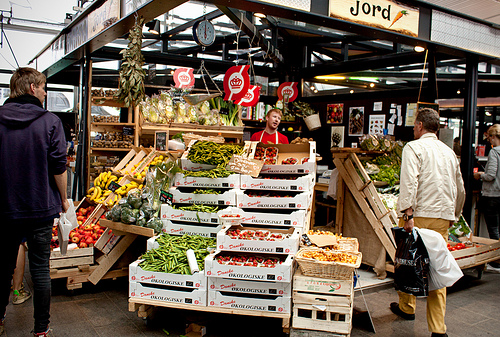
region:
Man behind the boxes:
[251, 110, 288, 143]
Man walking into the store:
[390, 109, 465, 334]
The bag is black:
[391, 224, 428, 295]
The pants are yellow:
[400, 216, 449, 332]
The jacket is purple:
[0, 95, 65, 226]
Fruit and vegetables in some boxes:
[50, 135, 360, 330]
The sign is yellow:
[330, 0, 415, 35]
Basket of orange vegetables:
[292, 245, 357, 275]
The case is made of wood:
[332, 148, 497, 275]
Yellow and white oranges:
[222, 62, 259, 108]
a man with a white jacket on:
[359, 114, 493, 217]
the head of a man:
[399, 86, 454, 166]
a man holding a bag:
[387, 148, 498, 281]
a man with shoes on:
[373, 258, 487, 328]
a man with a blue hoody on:
[10, 55, 136, 286]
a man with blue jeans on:
[0, 205, 61, 335]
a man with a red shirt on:
[251, 91, 316, 163]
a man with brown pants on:
[371, 206, 481, 334]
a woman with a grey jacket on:
[474, 122, 496, 199]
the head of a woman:
[482, 123, 498, 159]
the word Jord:
[348, 0, 392, 23]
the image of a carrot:
[390, 9, 408, 28]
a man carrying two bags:
[396, 113, 458, 334]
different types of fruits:
[76, 137, 351, 320]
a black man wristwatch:
[400, 212, 412, 222]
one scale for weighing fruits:
[192, 20, 220, 101]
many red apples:
[74, 217, 101, 247]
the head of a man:
[8, 68, 48, 101]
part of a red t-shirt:
[253, 131, 286, 146]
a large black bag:
[390, 224, 430, 293]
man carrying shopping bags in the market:
[393, 94, 465, 328]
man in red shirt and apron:
[249, 100, 293, 138]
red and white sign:
[217, 59, 252, 100]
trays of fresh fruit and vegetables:
[176, 139, 306, 313]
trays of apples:
[79, 220, 99, 259]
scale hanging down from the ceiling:
[194, 19, 226, 99]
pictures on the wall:
[325, 99, 367, 137]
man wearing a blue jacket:
[4, 98, 76, 225]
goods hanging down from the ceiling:
[114, 18, 148, 110]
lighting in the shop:
[408, 40, 425, 57]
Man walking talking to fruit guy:
[399, 108, 471, 333]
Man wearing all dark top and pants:
[2, 70, 68, 333]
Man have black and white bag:
[391, 100, 464, 333]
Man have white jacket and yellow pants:
[385, 105, 462, 333]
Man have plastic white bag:
[3, 66, 88, 333]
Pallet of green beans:
[131, 148, 213, 315]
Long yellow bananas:
[76, 163, 129, 209]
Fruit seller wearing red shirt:
[247, 105, 294, 153]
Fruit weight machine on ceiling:
[187, 13, 224, 113]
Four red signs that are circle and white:
[171, 66, 308, 111]